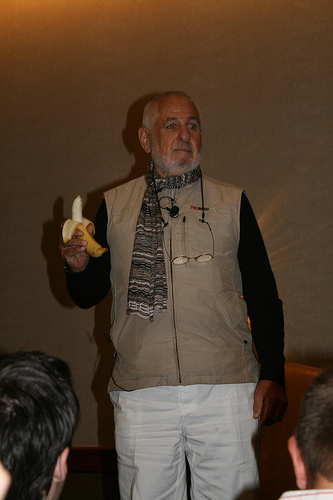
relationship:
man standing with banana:
[54, 83, 291, 499] [61, 193, 107, 258]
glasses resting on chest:
[159, 218, 215, 264] [115, 182, 234, 266]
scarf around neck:
[123, 157, 203, 321] [148, 162, 202, 190]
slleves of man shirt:
[242, 191, 281, 378] [46, 180, 281, 385]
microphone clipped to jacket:
[157, 195, 182, 222] [84, 175, 268, 382]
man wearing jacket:
[54, 83, 291, 499] [102, 176, 260, 395]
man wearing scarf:
[54, 83, 291, 499] [123, 157, 203, 321]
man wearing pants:
[54, 83, 291, 499] [108, 381, 262, 498]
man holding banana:
[54, 83, 291, 499] [61, 193, 107, 258]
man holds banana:
[61, 90, 290, 499] [39, 75, 291, 498]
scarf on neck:
[126, 164, 201, 318] [148, 167, 202, 186]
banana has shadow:
[57, 190, 107, 260] [54, 195, 65, 223]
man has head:
[261, 366, 331, 498] [279, 362, 332, 498]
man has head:
[1, 341, 86, 498] [5, 346, 90, 498]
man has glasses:
[61, 90, 290, 499] [159, 214, 220, 269]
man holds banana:
[54, 83, 291, 499] [56, 194, 108, 259]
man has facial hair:
[54, 83, 291, 499] [147, 133, 203, 175]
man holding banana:
[61, 90, 290, 499] [56, 194, 108, 259]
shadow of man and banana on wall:
[41, 89, 167, 498] [0, 1, 331, 444]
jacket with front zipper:
[102, 176, 260, 395] [166, 185, 182, 385]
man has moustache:
[54, 83, 291, 499] [173, 143, 192, 151]